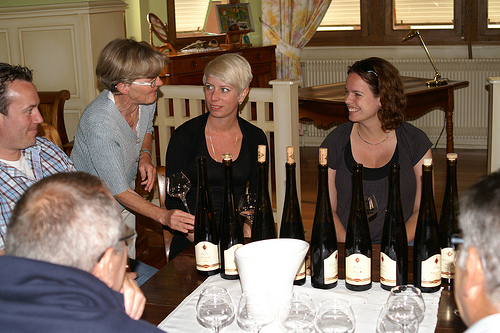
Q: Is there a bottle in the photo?
A: Yes, there is a bottle.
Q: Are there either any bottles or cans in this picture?
A: Yes, there is a bottle.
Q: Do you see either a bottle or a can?
A: Yes, there is a bottle.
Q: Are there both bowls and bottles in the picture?
A: No, there is a bottle but no bowls.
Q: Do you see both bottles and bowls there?
A: No, there is a bottle but no bowls.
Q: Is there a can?
A: No, there are no cans.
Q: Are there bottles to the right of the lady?
A: Yes, there is a bottle to the right of the lady.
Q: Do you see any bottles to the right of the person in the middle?
A: Yes, there is a bottle to the right of the lady.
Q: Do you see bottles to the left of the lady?
A: No, the bottle is to the right of the lady.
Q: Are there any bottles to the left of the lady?
A: No, the bottle is to the right of the lady.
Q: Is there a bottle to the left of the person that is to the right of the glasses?
A: No, the bottle is to the right of the lady.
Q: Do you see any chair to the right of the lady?
A: No, there is a bottle to the right of the lady.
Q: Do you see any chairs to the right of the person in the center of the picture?
A: No, there is a bottle to the right of the lady.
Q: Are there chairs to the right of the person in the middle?
A: No, there is a bottle to the right of the lady.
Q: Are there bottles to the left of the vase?
A: No, the bottle is to the right of the vase.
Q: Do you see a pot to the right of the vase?
A: No, there is a bottle to the right of the vase.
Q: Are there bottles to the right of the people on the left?
A: Yes, there is a bottle to the right of the people.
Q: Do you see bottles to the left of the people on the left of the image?
A: No, the bottle is to the right of the people.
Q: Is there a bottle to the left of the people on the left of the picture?
A: No, the bottle is to the right of the people.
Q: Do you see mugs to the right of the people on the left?
A: No, there is a bottle to the right of the people.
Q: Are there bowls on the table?
A: No, there is a bottle on the table.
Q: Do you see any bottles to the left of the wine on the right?
A: Yes, there is a bottle to the left of the wine.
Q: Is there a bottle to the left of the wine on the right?
A: Yes, there is a bottle to the left of the wine.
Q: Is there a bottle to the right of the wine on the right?
A: No, the bottle is to the left of the wine.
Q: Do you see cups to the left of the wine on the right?
A: No, there is a bottle to the left of the wine.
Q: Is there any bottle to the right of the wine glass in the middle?
A: Yes, there is a bottle to the right of the wine glass.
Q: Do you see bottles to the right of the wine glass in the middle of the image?
A: Yes, there is a bottle to the right of the wine glass.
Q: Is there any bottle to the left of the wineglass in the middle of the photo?
A: No, the bottle is to the right of the wine glass.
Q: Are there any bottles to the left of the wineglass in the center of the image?
A: No, the bottle is to the right of the wine glass.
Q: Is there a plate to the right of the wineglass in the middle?
A: No, there is a bottle to the right of the wine glass.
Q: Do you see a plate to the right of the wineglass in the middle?
A: No, there is a bottle to the right of the wine glass.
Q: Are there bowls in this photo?
A: No, there are no bowls.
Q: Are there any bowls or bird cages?
A: No, there are no bowls or bird cages.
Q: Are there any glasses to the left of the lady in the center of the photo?
A: Yes, there are glasses to the left of the lady.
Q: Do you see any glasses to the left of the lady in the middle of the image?
A: Yes, there are glasses to the left of the lady.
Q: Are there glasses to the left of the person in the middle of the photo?
A: Yes, there are glasses to the left of the lady.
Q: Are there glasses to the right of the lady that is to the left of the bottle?
A: No, the glasses are to the left of the lady.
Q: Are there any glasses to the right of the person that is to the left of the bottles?
A: No, the glasses are to the left of the lady.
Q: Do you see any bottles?
A: Yes, there is a bottle.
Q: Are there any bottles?
A: Yes, there is a bottle.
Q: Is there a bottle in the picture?
A: Yes, there is a bottle.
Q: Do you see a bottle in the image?
A: Yes, there is a bottle.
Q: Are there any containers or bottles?
A: Yes, there is a bottle.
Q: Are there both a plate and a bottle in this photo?
A: No, there is a bottle but no plates.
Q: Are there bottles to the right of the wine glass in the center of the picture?
A: Yes, there is a bottle to the right of the wineglass.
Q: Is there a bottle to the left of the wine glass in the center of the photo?
A: No, the bottle is to the right of the wineglass.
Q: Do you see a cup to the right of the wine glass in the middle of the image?
A: No, there is a bottle to the right of the wine glass.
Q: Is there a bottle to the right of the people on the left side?
A: Yes, there is a bottle to the right of the people.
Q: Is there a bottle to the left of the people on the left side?
A: No, the bottle is to the right of the people.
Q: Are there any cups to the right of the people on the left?
A: No, there is a bottle to the right of the people.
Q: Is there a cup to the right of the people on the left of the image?
A: No, there is a bottle to the right of the people.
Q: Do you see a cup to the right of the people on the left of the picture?
A: No, there is a bottle to the right of the people.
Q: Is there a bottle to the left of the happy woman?
A: Yes, there is a bottle to the left of the woman.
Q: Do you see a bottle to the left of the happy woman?
A: Yes, there is a bottle to the left of the woman.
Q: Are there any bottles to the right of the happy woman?
A: No, the bottle is to the left of the woman.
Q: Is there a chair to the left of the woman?
A: No, there is a bottle to the left of the woman.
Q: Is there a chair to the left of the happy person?
A: No, there is a bottle to the left of the woman.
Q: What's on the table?
A: The bottle is on the table.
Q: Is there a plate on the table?
A: No, there is a bottle on the table.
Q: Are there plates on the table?
A: No, there is a bottle on the table.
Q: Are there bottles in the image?
A: Yes, there is a bottle.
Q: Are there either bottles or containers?
A: Yes, there is a bottle.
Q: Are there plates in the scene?
A: No, there are no plates.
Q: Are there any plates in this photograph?
A: No, there are no plates.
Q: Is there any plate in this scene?
A: No, there are no plates.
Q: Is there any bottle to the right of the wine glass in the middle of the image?
A: Yes, there is a bottle to the right of the wine glass.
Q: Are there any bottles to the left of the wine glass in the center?
A: No, the bottle is to the right of the wineglass.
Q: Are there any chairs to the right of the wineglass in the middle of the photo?
A: No, there is a bottle to the right of the wine glass.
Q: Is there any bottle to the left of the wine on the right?
A: Yes, there is a bottle to the left of the wine.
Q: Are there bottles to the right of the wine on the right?
A: No, the bottle is to the left of the wine.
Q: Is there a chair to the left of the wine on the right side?
A: No, there is a bottle to the left of the wine.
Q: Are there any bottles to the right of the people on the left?
A: Yes, there is a bottle to the right of the people.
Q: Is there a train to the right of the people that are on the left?
A: No, there is a bottle to the right of the people.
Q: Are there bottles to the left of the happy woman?
A: Yes, there is a bottle to the left of the woman.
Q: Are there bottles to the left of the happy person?
A: Yes, there is a bottle to the left of the woman.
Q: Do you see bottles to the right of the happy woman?
A: No, the bottle is to the left of the woman.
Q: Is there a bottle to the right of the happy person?
A: No, the bottle is to the left of the woman.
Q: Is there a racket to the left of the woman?
A: No, there is a bottle to the left of the woman.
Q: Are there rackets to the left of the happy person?
A: No, there is a bottle to the left of the woman.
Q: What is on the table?
A: The bottle is on the table.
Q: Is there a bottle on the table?
A: Yes, there is a bottle on the table.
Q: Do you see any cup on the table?
A: No, there is a bottle on the table.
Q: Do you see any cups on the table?
A: No, there is a bottle on the table.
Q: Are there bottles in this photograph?
A: Yes, there is a bottle.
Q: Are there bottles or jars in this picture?
A: Yes, there is a bottle.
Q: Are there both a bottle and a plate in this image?
A: No, there is a bottle but no plates.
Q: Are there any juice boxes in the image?
A: No, there are no juice boxes.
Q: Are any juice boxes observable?
A: No, there are no juice boxes.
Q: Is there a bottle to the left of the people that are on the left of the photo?
A: No, the bottle is to the right of the people.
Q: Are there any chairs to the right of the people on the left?
A: No, there is a bottle to the right of the people.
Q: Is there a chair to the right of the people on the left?
A: No, there is a bottle to the right of the people.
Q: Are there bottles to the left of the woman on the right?
A: Yes, there is a bottle to the left of the woman.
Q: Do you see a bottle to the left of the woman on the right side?
A: Yes, there is a bottle to the left of the woman.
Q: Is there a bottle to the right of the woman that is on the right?
A: No, the bottle is to the left of the woman.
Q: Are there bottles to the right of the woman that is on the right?
A: No, the bottle is to the left of the woman.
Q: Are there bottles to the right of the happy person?
A: No, the bottle is to the left of the woman.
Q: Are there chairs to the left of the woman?
A: No, there is a bottle to the left of the woman.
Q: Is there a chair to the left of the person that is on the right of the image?
A: No, there is a bottle to the left of the woman.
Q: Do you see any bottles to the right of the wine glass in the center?
A: Yes, there is a bottle to the right of the wineglass.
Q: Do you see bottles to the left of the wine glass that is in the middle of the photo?
A: No, the bottle is to the right of the wineglass.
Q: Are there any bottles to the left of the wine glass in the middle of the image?
A: No, the bottle is to the right of the wineglass.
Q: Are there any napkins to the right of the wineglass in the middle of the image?
A: No, there is a bottle to the right of the wine glass.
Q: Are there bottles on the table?
A: Yes, there is a bottle on the table.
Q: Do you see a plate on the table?
A: No, there is a bottle on the table.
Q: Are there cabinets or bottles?
A: Yes, there is a bottle.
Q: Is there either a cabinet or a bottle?
A: Yes, there is a bottle.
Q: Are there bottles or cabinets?
A: Yes, there is a bottle.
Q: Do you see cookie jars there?
A: No, there are no cookie jars.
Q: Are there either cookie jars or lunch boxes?
A: No, there are no cookie jars or lunch boxes.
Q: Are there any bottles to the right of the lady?
A: Yes, there is a bottle to the right of the lady.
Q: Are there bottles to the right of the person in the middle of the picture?
A: Yes, there is a bottle to the right of the lady.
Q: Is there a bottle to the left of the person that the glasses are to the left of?
A: No, the bottle is to the right of the lady.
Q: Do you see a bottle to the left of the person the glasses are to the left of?
A: No, the bottle is to the right of the lady.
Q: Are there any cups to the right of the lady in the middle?
A: No, there is a bottle to the right of the lady.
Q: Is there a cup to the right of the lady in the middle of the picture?
A: No, there is a bottle to the right of the lady.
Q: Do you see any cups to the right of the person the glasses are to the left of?
A: No, there is a bottle to the right of the lady.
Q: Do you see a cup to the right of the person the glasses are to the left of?
A: No, there is a bottle to the right of the lady.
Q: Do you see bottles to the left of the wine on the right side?
A: Yes, there is a bottle to the left of the wine.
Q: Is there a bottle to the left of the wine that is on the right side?
A: Yes, there is a bottle to the left of the wine.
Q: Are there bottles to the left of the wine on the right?
A: Yes, there is a bottle to the left of the wine.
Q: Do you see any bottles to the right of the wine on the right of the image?
A: No, the bottle is to the left of the wine.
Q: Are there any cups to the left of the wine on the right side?
A: No, there is a bottle to the left of the wine.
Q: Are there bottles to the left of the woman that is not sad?
A: Yes, there is a bottle to the left of the woman.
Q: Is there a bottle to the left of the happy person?
A: Yes, there is a bottle to the left of the woman.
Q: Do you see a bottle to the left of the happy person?
A: Yes, there is a bottle to the left of the woman.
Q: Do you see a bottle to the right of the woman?
A: No, the bottle is to the left of the woman.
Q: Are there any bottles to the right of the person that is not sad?
A: No, the bottle is to the left of the woman.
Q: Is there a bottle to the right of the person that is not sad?
A: No, the bottle is to the left of the woman.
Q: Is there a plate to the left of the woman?
A: No, there is a bottle to the left of the woman.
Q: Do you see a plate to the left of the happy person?
A: No, there is a bottle to the left of the woman.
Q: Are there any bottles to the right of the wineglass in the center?
A: Yes, there is a bottle to the right of the wine glass.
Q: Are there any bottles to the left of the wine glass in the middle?
A: No, the bottle is to the right of the wineglass.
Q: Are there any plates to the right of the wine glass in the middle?
A: No, there is a bottle to the right of the wine glass.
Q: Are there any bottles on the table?
A: Yes, there is a bottle on the table.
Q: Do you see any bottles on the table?
A: Yes, there is a bottle on the table.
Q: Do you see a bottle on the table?
A: Yes, there is a bottle on the table.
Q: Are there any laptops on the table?
A: No, there is a bottle on the table.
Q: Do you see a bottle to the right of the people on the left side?
A: Yes, there is a bottle to the right of the people.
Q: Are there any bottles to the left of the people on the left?
A: No, the bottle is to the right of the people.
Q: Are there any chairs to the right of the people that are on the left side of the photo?
A: No, there is a bottle to the right of the people.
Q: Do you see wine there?
A: Yes, there is wine.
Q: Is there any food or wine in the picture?
A: Yes, there is wine.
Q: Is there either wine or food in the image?
A: Yes, there is wine.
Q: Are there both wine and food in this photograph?
A: No, there is wine but no food.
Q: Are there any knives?
A: No, there are no knives.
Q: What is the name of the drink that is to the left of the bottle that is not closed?
A: The drink is wine.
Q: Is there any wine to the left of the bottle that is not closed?
A: Yes, there is wine to the left of the bottle.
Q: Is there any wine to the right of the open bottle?
A: No, the wine is to the left of the bottle.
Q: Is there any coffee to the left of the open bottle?
A: No, there is wine to the left of the bottle.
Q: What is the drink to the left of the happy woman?
A: The drink is wine.